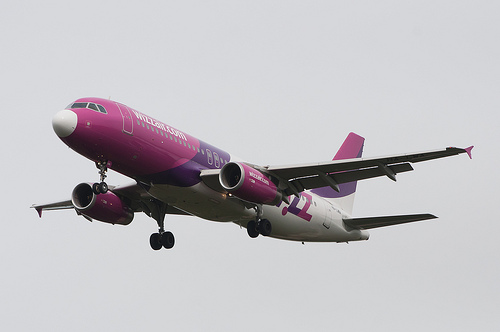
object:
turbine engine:
[218, 159, 284, 208]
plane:
[29, 96, 474, 250]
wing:
[199, 145, 476, 197]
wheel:
[99, 181, 109, 194]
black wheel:
[259, 218, 272, 236]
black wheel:
[247, 220, 259, 239]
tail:
[309, 131, 366, 216]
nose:
[52, 109, 79, 138]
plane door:
[114, 101, 134, 134]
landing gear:
[135, 192, 272, 251]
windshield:
[70, 102, 107, 115]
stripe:
[151, 139, 230, 187]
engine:
[71, 182, 135, 226]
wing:
[28, 184, 143, 218]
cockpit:
[66, 101, 107, 114]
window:
[137, 119, 140, 125]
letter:
[132, 110, 143, 120]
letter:
[145, 116, 156, 126]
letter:
[166, 126, 174, 135]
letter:
[170, 128, 174, 134]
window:
[201, 148, 205, 155]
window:
[169, 134, 173, 140]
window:
[155, 128, 159, 135]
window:
[146, 123, 149, 129]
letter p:
[288, 191, 313, 222]